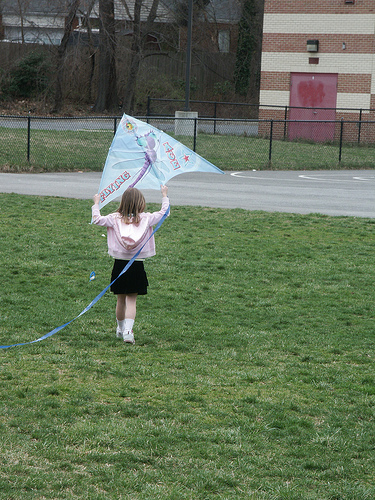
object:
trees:
[91, 0, 119, 113]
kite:
[90, 112, 227, 225]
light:
[306, 39, 319, 53]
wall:
[258, 0, 375, 143]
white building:
[263, 14, 375, 34]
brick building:
[258, 0, 375, 144]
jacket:
[90, 197, 170, 259]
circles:
[353, 175, 375, 180]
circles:
[299, 173, 375, 181]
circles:
[230, 170, 375, 182]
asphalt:
[0, 168, 374, 218]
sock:
[124, 319, 134, 332]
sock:
[115, 317, 125, 330]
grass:
[0, 192, 375, 500]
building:
[1, 0, 243, 85]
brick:
[264, 1, 375, 14]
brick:
[262, 32, 306, 53]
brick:
[346, 34, 375, 54]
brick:
[260, 71, 291, 91]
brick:
[337, 73, 371, 93]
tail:
[0, 200, 171, 349]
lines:
[229, 170, 373, 183]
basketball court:
[0, 168, 374, 219]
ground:
[0, 103, 375, 500]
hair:
[116, 188, 145, 225]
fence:
[0, 116, 375, 167]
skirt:
[110, 259, 149, 295]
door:
[287, 71, 339, 143]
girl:
[91, 184, 170, 344]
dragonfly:
[110, 129, 162, 188]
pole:
[184, 1, 193, 108]